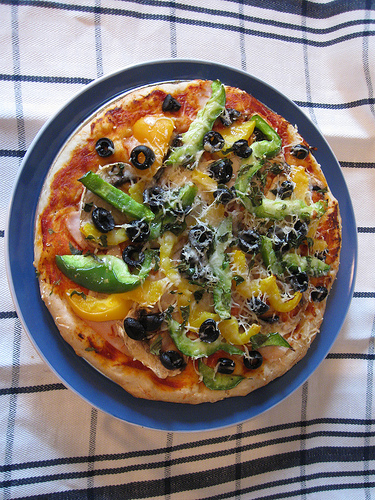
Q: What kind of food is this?
A: Pizza.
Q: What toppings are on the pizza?
A: Vegetables.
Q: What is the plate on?
A: Tablecloth.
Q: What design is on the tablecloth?
A: Square blue designs.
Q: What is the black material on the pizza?
A: Olives.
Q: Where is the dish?
A: On a tablecloth.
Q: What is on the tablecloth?
A: A dish with pizza.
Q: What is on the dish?
A: A pizza.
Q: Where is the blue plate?
A: On the tablecloth.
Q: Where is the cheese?
A: On the pizza.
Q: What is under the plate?
A: A blue and white tablecloth.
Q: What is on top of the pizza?
A: Toppings.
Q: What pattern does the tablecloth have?
A: Blue lines.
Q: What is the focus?
A: Pizza pie.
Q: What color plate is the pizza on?
A: Blue.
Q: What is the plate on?
A: Tablecloth.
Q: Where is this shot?
A: Table.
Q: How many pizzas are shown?
A: 1.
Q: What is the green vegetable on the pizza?
A: Green peppers.